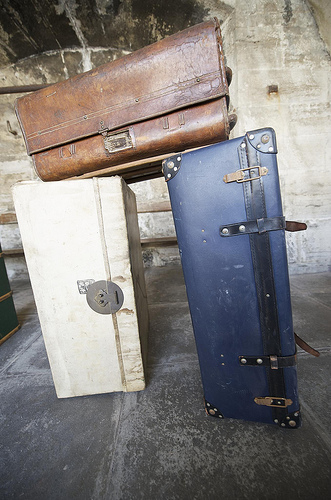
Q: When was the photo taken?
A: During the day.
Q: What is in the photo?
A: Luggage.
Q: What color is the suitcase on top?
A: Brown.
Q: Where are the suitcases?
A: On the sidewalk.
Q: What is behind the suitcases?
A: The wall.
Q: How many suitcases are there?
A: Three.